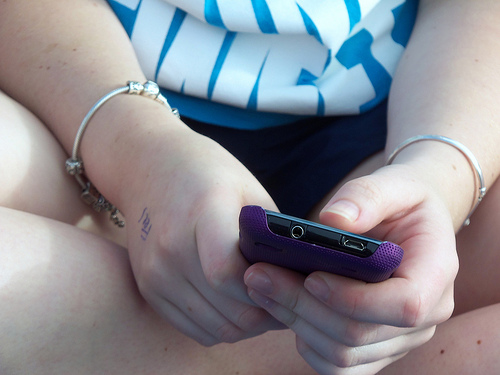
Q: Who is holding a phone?
A: A woman.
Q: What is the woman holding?
A: A phone.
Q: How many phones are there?
A: One.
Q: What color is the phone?
A: Purple.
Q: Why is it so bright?
A: Sunny.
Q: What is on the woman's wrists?
A: Bracelets.